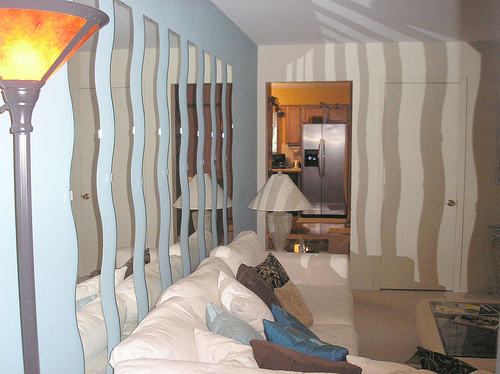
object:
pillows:
[233, 260, 284, 311]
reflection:
[172, 152, 238, 242]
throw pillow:
[219, 272, 266, 322]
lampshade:
[248, 172, 313, 212]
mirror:
[160, 82, 234, 248]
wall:
[253, 39, 500, 295]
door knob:
[443, 194, 455, 207]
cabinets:
[276, 103, 348, 154]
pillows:
[212, 269, 277, 337]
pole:
[2, 89, 40, 374]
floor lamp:
[1, 0, 111, 372]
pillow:
[263, 319, 348, 361]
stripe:
[268, 0, 500, 289]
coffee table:
[413, 298, 498, 373]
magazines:
[435, 298, 500, 332]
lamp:
[176, 171, 232, 249]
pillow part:
[259, 318, 347, 363]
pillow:
[404, 345, 478, 373]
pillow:
[193, 326, 259, 368]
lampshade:
[0, 2, 111, 82]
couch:
[110, 230, 445, 374]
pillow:
[266, 313, 346, 358]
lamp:
[247, 170, 313, 254]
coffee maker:
[272, 154, 286, 170]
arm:
[270, 252, 351, 282]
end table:
[266, 238, 331, 253]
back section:
[106, 231, 264, 361]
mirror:
[264, 94, 281, 170]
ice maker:
[305, 149, 319, 167]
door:
[356, 83, 466, 295]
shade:
[246, 170, 315, 216]